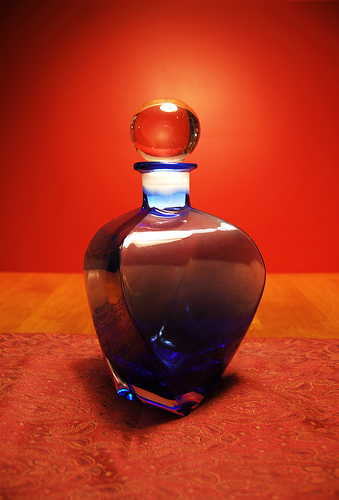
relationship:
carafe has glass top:
[81, 158, 268, 415] [126, 96, 201, 158]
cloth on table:
[2, 328, 337, 494] [1, 270, 338, 336]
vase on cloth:
[83, 97, 269, 412] [2, 328, 337, 494]